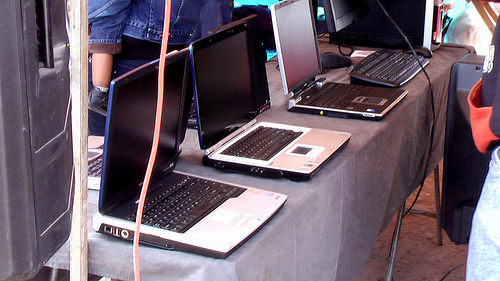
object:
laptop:
[89, 43, 292, 262]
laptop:
[184, 11, 356, 184]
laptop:
[265, 0, 414, 125]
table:
[40, 23, 478, 280]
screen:
[103, 54, 187, 207]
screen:
[192, 18, 271, 146]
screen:
[275, 0, 321, 92]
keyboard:
[122, 172, 249, 236]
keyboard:
[217, 122, 307, 163]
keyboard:
[305, 79, 376, 112]